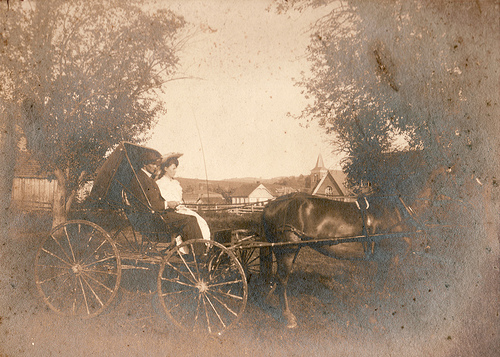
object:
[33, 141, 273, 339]
buggy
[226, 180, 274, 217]
building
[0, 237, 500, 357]
ground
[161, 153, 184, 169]
hat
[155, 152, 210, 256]
woman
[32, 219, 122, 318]
rear wheel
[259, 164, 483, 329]
brown horse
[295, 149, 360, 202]
building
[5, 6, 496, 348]
photo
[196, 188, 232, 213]
barn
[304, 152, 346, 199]
churck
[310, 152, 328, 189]
steeple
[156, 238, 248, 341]
wheel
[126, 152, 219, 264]
man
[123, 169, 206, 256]
suit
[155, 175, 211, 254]
dress